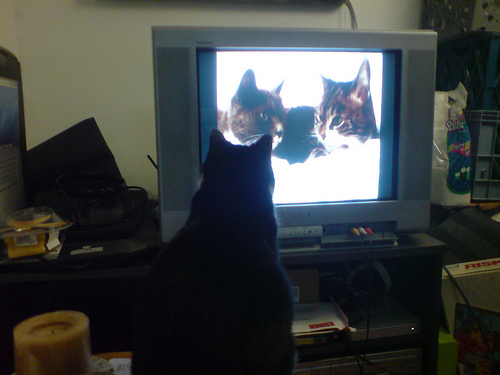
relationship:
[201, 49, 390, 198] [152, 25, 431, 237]
cats on tv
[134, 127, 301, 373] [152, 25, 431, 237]
cat watching tv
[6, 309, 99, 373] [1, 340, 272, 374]
candle on table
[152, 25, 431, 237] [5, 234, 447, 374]
tv on stand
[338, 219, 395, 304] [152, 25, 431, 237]
cords plugged into tv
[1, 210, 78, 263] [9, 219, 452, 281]
dvd on shelf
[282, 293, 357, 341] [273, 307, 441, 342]
papers on shelf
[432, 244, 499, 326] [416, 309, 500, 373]
box on floor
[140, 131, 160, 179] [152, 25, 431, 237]
cord behind tv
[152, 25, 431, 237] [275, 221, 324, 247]
tv has knobs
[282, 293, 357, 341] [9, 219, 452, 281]
magazine on top of shelf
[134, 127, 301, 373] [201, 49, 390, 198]
cat watching cats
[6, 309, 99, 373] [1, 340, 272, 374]
candle sitting on table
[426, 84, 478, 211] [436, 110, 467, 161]
bag of toilet paper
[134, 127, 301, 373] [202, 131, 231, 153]
cat has ear